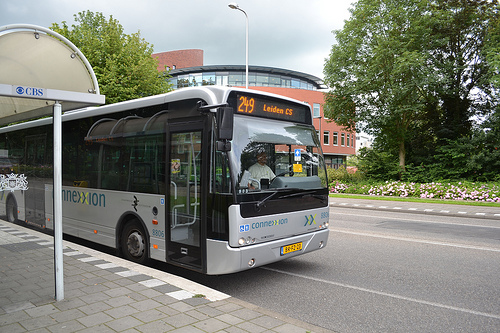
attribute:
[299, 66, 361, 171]
building — large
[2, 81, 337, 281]
bus — black, silver, gray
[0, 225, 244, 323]
sidewalk — white, gray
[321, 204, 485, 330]
street — paved, clean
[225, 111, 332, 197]
windshield — large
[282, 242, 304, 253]
license plate — yellow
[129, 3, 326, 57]
sky — dark gray, cloudy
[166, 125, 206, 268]
door — glass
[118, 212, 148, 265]
tire — black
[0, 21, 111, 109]
awning — white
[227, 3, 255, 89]
pole — long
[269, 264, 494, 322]
line — white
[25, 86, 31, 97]
letter c — blue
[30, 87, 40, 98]
letter b — blue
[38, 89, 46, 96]
letter s — blue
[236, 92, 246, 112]
number 2 — orange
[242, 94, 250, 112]
number 4 — orange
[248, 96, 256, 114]
number 9 — orange